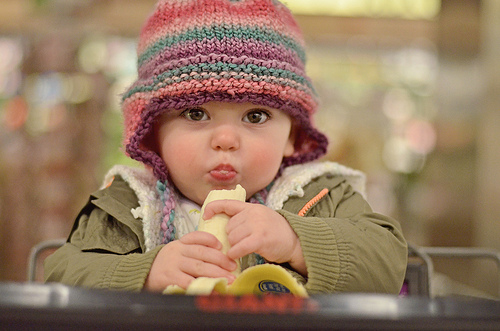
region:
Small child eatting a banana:
[83, 2, 408, 312]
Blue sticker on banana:
[249, 274, 303, 296]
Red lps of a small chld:
[202, 161, 247, 188]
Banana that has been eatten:
[192, 183, 299, 298]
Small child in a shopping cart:
[35, 10, 362, 313]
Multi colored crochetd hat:
[130, 4, 342, 121]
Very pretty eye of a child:
[237, 106, 279, 131]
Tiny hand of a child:
[201, 193, 308, 259]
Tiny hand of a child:
[142, 221, 252, 287]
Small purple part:
[391, 273, 417, 299]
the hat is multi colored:
[115, 0, 328, 187]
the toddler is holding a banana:
[177, 180, 277, 302]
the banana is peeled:
[165, 186, 301, 301]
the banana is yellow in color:
[195, 185, 246, 291]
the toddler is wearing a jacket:
[38, 150, 415, 320]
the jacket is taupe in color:
[28, 170, 415, 308]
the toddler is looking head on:
[153, 80, 298, 200]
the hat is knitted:
[111, 1, 331, 172]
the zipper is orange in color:
[295, 186, 335, 219]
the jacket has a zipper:
[296, 184, 332, 222]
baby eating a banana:
[101, 18, 418, 308]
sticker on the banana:
[261, 280, 286, 297]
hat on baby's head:
[141, 9, 322, 126]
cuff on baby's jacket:
[297, 205, 340, 292]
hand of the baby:
[228, 204, 288, 263]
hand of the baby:
[155, 224, 210, 286]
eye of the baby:
[243, 108, 292, 128]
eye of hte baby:
[181, 97, 208, 130]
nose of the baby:
[218, 133, 243, 146]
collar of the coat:
[85, 194, 117, 233]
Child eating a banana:
[42, 5, 411, 296]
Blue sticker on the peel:
[253, 275, 290, 303]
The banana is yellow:
[170, 171, 300, 299]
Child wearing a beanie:
[114, 5, 333, 208]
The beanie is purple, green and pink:
[114, 4, 324, 164]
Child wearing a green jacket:
[57, 5, 417, 292]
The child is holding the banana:
[161, 179, 288, 283]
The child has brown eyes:
[129, 4, 309, 194]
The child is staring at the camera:
[118, 10, 320, 203]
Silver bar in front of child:
[21, 265, 430, 330]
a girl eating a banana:
[30, 3, 425, 293]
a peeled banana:
[166, 186, 306, 301]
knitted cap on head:
[122, 4, 317, 97]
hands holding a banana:
[146, 183, 295, 292]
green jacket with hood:
[297, 159, 409, 298]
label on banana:
[251, 274, 298, 294]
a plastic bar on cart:
[5, 295, 497, 326]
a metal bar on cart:
[415, 230, 498, 295]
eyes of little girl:
[165, 95, 281, 131]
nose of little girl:
[212, 124, 244, 160]